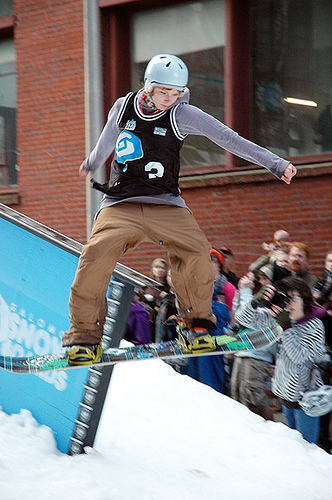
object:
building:
[0, 1, 329, 301]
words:
[33, 328, 51, 356]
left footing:
[66, 342, 103, 366]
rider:
[60, 53, 298, 369]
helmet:
[142, 52, 193, 94]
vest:
[155, 114, 183, 184]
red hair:
[285, 241, 310, 271]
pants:
[50, 192, 217, 345]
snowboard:
[0, 322, 283, 374]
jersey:
[95, 90, 194, 200]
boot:
[61, 329, 114, 367]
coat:
[238, 286, 328, 404]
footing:
[177, 321, 216, 353]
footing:
[66, 342, 102, 365]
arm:
[185, 106, 279, 171]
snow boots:
[59, 323, 227, 354]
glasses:
[290, 289, 303, 300]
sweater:
[233, 301, 328, 402]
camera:
[252, 269, 303, 317]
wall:
[0, 204, 160, 458]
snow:
[2, 336, 329, 499]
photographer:
[233, 277, 331, 444]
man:
[280, 239, 324, 301]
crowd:
[143, 229, 330, 445]